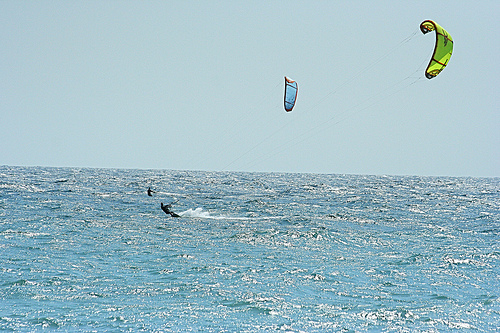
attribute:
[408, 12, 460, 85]
kite — green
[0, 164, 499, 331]
water — green, blue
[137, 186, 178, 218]
people — water skiing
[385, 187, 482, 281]
surface — blue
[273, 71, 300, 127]
object — in the picture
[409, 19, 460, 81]
sail — green, in mid air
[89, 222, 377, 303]
ocean — choppy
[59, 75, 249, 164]
horizon — in background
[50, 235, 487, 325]
water — blue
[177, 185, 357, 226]
wavy water — blue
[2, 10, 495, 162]
clear sky — above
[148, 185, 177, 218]
men — parasailing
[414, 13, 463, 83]
elephant — in the picture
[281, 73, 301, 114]
water kite — blue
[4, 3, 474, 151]
sky — blue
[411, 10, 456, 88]
kite — green